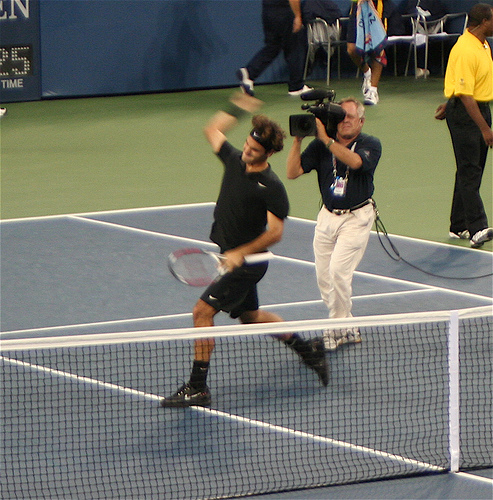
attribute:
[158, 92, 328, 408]
man — playing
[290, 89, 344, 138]
video camera — large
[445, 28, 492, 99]
shirt — yellow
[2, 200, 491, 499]
tennis court — blue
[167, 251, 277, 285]
racket — white, orange, black, red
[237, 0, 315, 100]
person — moving, walking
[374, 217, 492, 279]
cable — black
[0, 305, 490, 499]
net — black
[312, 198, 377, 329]
pants — white, khaki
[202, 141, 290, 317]
clothing — black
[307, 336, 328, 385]
shoe — black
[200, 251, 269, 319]
shorts — black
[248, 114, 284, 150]
hair — brown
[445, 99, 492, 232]
pants — black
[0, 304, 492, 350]
top — white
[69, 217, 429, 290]
line — white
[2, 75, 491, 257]
part — green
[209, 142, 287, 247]
shirt — pitch black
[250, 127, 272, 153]
headband — black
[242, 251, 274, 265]
handle — white